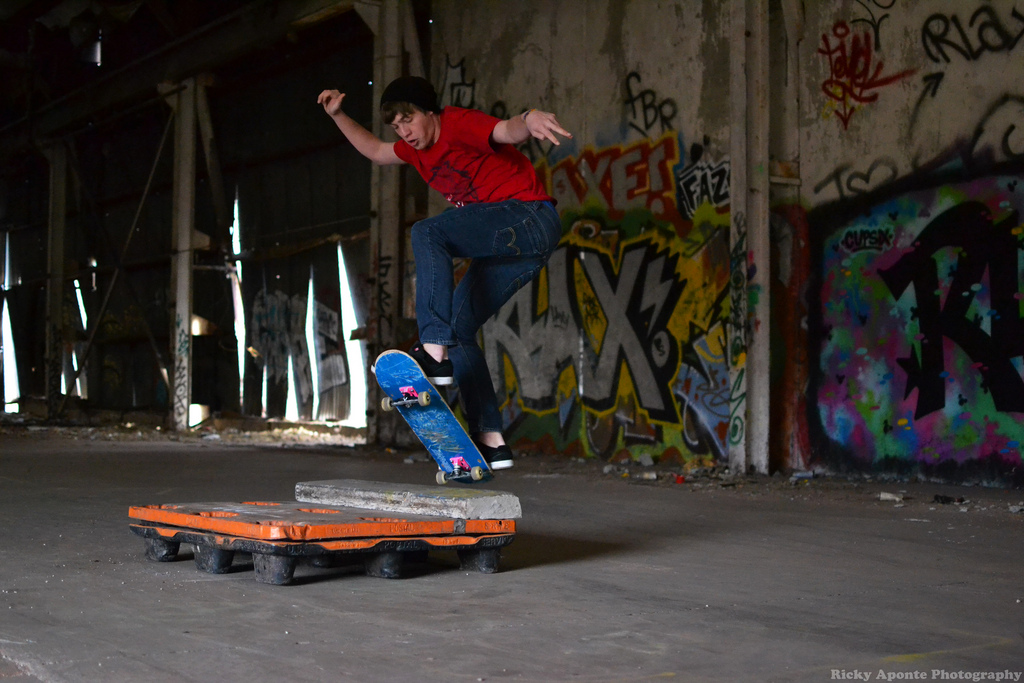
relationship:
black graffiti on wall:
[884, 201, 990, 424] [568, 20, 970, 492]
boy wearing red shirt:
[309, 68, 569, 479] [384, 105, 554, 212]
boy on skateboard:
[309, 68, 569, 479] [207, 351, 651, 565]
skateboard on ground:
[360, 351, 503, 486] [169, 449, 561, 599]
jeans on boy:
[413, 202, 552, 417] [354, 230, 527, 466]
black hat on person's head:
[373, 74, 440, 111] [361, 80, 468, 174]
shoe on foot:
[397, 348, 464, 401] [399, 324, 486, 435]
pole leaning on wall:
[160, 61, 204, 440] [52, 7, 1016, 481]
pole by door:
[33, 123, 148, 471] [37, 99, 413, 449]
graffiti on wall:
[414, 138, 1011, 501] [382, 0, 1022, 498]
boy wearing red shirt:
[309, 68, 569, 479] [359, 96, 554, 213]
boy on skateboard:
[309, 68, 569, 479] [353, 348, 520, 521]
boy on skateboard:
[309, 68, 569, 479] [348, 337, 498, 504]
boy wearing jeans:
[309, 68, 569, 479] [413, 202, 552, 417]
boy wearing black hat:
[309, 68, 569, 479] [374, 67, 442, 130]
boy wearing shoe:
[309, 68, 569, 479] [369, 342, 456, 391]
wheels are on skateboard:
[257, 551, 294, 588] [376, 351, 500, 485]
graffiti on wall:
[774, 77, 1020, 499] [0, 1, 1005, 513]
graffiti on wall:
[774, 77, 1019, 499] [52, 7, 1016, 481]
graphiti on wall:
[477, 194, 763, 469] [0, 1, 1005, 513]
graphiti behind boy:
[477, 194, 763, 469] [309, 68, 569, 479]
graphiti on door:
[207, 334, 387, 412] [169, 68, 401, 440]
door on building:
[169, 68, 401, 440] [0, 0, 1009, 508]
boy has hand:
[309, 68, 569, 479] [512, 90, 573, 162]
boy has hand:
[309, 68, 569, 479] [309, 68, 361, 127]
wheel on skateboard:
[406, 379, 437, 416] [369, 321, 503, 509]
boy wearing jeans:
[309, 68, 569, 479] [402, 202, 569, 449]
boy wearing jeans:
[309, 68, 569, 479] [410, 202, 571, 432]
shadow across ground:
[259, 487, 756, 580] [6, 418, 1018, 678]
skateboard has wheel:
[360, 351, 503, 486] [391, 375, 437, 419]